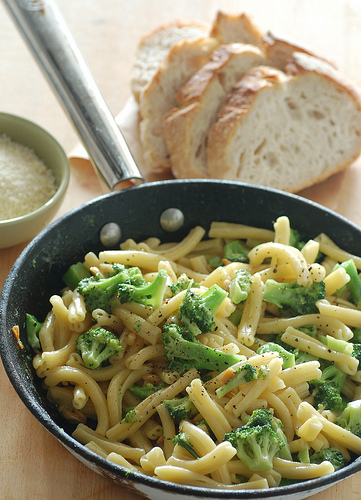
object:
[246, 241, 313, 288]
macaroni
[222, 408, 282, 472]
broccoli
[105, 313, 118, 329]
pepper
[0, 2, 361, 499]
pan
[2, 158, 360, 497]
counter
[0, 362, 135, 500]
wood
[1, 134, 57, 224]
rice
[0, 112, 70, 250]
bowl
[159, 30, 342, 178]
slice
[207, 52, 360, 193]
bread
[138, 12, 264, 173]
slice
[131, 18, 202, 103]
slice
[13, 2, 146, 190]
handle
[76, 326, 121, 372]
broccoli piece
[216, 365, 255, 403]
broccoli piece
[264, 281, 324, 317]
broccoli piece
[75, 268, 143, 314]
broccoli piece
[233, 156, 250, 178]
holes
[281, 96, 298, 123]
holes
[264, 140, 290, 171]
holes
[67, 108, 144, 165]
napkin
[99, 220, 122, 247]
bolts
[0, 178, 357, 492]
pot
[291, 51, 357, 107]
crust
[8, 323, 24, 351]
garlic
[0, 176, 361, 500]
dish